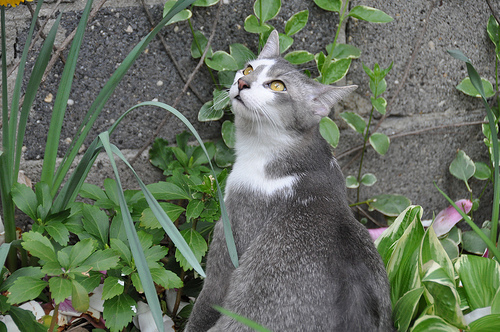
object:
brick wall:
[0, 11, 222, 150]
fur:
[220, 83, 335, 227]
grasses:
[0, 1, 238, 332]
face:
[228, 58, 305, 119]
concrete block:
[376, 36, 468, 189]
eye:
[263, 76, 289, 93]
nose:
[236, 76, 251, 91]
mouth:
[229, 90, 254, 111]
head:
[228, 28, 360, 134]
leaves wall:
[432, 46, 500, 163]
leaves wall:
[0, 109, 186, 332]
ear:
[307, 82, 360, 107]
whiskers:
[201, 87, 280, 135]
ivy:
[157, 0, 394, 158]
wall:
[4, 4, 499, 246]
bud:
[432, 197, 473, 237]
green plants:
[1, 152, 221, 329]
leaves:
[447, 143, 489, 190]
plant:
[375, 204, 495, 316]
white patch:
[230, 114, 262, 181]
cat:
[191, 29, 394, 329]